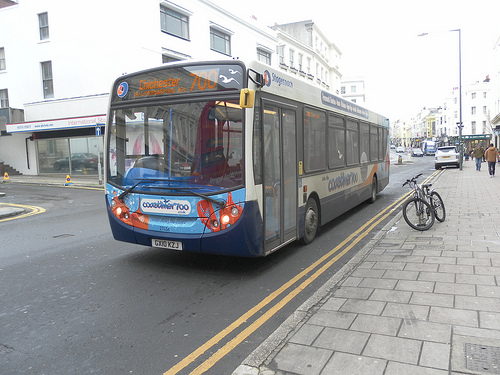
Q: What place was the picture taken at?
A: It was taken at the city.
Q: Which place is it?
A: It is a city.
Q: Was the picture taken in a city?
A: Yes, it was taken in a city.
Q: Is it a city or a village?
A: It is a city.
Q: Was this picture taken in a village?
A: No, the picture was taken in a city.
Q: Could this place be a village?
A: No, it is a city.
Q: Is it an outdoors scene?
A: Yes, it is outdoors.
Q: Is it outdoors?
A: Yes, it is outdoors.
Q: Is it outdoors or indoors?
A: It is outdoors.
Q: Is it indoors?
A: No, it is outdoors.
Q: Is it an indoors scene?
A: No, it is outdoors.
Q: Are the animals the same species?
A: Yes, all the animals are seagulls.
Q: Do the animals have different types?
A: No, all the animals are sea gulls.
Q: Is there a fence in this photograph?
A: No, there are no fences.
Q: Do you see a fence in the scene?
A: No, there are no fences.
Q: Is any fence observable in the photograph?
A: No, there are no fences.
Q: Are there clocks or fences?
A: No, there are no fences or clocks.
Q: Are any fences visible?
A: No, there are no fences.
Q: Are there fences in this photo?
A: No, there are no fences.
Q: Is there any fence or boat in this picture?
A: No, there are no fences or boats.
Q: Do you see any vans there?
A: No, there are no vans.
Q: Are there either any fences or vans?
A: No, there are no vans or fences.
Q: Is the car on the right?
A: Yes, the car is on the right of the image.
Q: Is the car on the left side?
A: No, the car is on the right of the image.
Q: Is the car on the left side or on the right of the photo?
A: The car is on the right of the image.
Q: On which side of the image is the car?
A: The car is on the right of the image.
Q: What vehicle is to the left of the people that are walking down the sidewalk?
A: The vehicle is a car.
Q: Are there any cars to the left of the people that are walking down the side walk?
A: Yes, there is a car to the left of the people.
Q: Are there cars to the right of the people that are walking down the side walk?
A: No, the car is to the left of the people.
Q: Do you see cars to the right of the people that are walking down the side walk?
A: No, the car is to the left of the people.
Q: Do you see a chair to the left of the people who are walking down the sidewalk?
A: No, there is a car to the left of the people.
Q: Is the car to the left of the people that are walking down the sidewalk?
A: Yes, the car is to the left of the people.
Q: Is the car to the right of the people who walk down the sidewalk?
A: No, the car is to the left of the people.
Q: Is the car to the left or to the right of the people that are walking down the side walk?
A: The car is to the left of the people.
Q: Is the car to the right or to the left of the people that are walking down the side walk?
A: The car is to the left of the people.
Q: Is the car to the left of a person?
A: Yes, the car is to the left of a person.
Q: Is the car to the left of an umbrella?
A: No, the car is to the left of a person.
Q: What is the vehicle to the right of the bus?
A: The vehicle is a car.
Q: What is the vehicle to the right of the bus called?
A: The vehicle is a car.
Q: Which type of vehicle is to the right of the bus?
A: The vehicle is a car.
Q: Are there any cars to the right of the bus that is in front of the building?
A: Yes, there is a car to the right of the bus.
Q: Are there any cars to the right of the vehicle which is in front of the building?
A: Yes, there is a car to the right of the bus.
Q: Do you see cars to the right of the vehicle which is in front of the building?
A: Yes, there is a car to the right of the bus.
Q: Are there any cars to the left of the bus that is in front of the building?
A: No, the car is to the right of the bus.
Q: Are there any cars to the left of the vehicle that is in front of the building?
A: No, the car is to the right of the bus.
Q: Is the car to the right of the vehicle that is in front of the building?
A: Yes, the car is to the right of the bus.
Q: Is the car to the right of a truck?
A: No, the car is to the right of the bus.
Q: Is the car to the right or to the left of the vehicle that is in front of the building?
A: The car is to the right of the bus.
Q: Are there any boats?
A: No, there are no boats.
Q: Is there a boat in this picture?
A: No, there are no boats.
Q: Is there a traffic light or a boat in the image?
A: No, there are no boats or traffic lights.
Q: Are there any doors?
A: Yes, there is a door.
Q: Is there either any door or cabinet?
A: Yes, there is a door.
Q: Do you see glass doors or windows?
A: Yes, there is a glass door.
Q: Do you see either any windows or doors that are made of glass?
A: Yes, the door is made of glass.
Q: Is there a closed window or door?
A: Yes, there is a closed door.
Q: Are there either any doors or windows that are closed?
A: Yes, the door is closed.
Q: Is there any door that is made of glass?
A: Yes, there is a door that is made of glass.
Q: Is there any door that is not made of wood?
A: Yes, there is a door that is made of glass.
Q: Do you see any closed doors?
A: Yes, there is a closed door.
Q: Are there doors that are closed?
A: Yes, there is a door that is closed.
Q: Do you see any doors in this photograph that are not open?
A: Yes, there is an closed door.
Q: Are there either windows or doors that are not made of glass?
A: No, there is a door but it is made of glass.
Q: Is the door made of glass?
A: Yes, the door is made of glass.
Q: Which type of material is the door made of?
A: The door is made of glass.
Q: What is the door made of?
A: The door is made of glass.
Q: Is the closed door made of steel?
A: No, the door is made of glass.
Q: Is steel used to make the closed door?
A: No, the door is made of glass.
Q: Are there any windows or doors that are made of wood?
A: No, there is a door but it is made of glass.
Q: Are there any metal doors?
A: No, there is a door but it is made of glass.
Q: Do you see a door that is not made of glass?
A: No, there is a door but it is made of glass.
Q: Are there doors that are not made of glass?
A: No, there is a door but it is made of glass.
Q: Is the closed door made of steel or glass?
A: The door is made of glass.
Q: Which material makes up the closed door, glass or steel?
A: The door is made of glass.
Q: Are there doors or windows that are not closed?
A: No, there is a door but it is closed.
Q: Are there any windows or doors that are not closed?
A: No, there is a door but it is closed.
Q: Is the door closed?
A: Yes, the door is closed.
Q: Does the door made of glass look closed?
A: Yes, the door is closed.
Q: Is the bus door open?
A: No, the door is closed.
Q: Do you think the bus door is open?
A: No, the door is closed.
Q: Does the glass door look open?
A: No, the door is closed.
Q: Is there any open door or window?
A: No, there is a door but it is closed.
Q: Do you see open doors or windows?
A: No, there is a door but it is closed.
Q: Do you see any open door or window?
A: No, there is a door but it is closed.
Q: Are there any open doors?
A: No, there is a door but it is closed.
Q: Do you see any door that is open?
A: No, there is a door but it is closed.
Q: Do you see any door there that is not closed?
A: No, there is a door but it is closed.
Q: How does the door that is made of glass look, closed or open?
A: The door is closed.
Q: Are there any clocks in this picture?
A: No, there are no clocks.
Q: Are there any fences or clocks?
A: No, there are no clocks or fences.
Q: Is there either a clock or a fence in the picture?
A: No, there are no clocks or fences.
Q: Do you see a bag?
A: No, there are no bags.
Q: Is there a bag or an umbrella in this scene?
A: No, there are no bags or umbrellas.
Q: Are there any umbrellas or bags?
A: No, there are no bags or umbrellas.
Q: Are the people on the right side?
A: Yes, the people are on the right of the image.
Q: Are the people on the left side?
A: No, the people are on the right of the image.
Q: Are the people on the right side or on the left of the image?
A: The people are on the right of the image.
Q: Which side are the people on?
A: The people are on the right of the image.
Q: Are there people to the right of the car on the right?
A: Yes, there are people to the right of the car.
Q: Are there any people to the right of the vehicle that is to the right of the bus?
A: Yes, there are people to the right of the car.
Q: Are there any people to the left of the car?
A: No, the people are to the right of the car.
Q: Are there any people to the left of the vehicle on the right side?
A: No, the people are to the right of the car.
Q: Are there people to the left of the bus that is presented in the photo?
A: No, the people are to the right of the bus.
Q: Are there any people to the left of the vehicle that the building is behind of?
A: No, the people are to the right of the bus.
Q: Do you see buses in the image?
A: Yes, there is a bus.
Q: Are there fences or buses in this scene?
A: Yes, there is a bus.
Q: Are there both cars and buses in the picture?
A: Yes, there are both a bus and a car.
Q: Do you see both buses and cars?
A: Yes, there are both a bus and a car.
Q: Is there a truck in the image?
A: No, there are no trucks.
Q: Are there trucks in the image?
A: No, there are no trucks.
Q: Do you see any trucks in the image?
A: No, there are no trucks.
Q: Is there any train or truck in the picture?
A: No, there are no trucks or trains.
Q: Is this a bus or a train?
A: This is a bus.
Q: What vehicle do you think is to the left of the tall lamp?
A: The vehicle is a bus.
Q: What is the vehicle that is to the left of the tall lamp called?
A: The vehicle is a bus.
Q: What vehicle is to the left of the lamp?
A: The vehicle is a bus.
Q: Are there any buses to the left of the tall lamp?
A: Yes, there is a bus to the left of the lamp.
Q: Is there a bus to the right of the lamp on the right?
A: No, the bus is to the left of the lamp.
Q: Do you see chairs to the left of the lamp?
A: No, there is a bus to the left of the lamp.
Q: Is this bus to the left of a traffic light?
A: No, the bus is to the left of a lamp.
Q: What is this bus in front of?
A: The bus is in front of the building.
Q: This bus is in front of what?
A: The bus is in front of the building.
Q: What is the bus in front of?
A: The bus is in front of the building.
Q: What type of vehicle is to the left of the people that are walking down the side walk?
A: The vehicle is a bus.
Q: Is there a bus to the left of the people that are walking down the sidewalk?
A: Yes, there is a bus to the left of the people.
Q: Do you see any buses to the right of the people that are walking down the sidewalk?
A: No, the bus is to the left of the people.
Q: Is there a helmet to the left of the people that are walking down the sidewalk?
A: No, there is a bus to the left of the people.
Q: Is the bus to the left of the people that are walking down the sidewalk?
A: Yes, the bus is to the left of the people.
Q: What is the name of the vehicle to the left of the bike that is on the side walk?
A: The vehicle is a bus.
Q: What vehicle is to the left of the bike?
A: The vehicle is a bus.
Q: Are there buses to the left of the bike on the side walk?
A: Yes, there is a bus to the left of the bike.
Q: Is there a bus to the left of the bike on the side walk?
A: Yes, there is a bus to the left of the bike.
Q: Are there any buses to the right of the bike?
A: No, the bus is to the left of the bike.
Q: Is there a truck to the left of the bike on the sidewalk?
A: No, there is a bus to the left of the bike.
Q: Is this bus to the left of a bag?
A: No, the bus is to the left of the bike.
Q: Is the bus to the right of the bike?
A: No, the bus is to the left of the bike.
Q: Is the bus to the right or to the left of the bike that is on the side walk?
A: The bus is to the left of the bike.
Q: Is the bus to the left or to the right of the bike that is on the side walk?
A: The bus is to the left of the bike.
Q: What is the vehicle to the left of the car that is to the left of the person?
A: The vehicle is a bus.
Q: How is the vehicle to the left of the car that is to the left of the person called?
A: The vehicle is a bus.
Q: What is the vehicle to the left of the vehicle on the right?
A: The vehicle is a bus.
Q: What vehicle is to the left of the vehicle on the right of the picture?
A: The vehicle is a bus.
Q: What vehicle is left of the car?
A: The vehicle is a bus.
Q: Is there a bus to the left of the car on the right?
A: Yes, there is a bus to the left of the car.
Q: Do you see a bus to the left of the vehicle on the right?
A: Yes, there is a bus to the left of the car.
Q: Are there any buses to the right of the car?
A: No, the bus is to the left of the car.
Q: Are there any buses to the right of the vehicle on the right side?
A: No, the bus is to the left of the car.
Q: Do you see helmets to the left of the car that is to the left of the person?
A: No, there is a bus to the left of the car.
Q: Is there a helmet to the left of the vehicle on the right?
A: No, there is a bus to the left of the car.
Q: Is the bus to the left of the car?
A: Yes, the bus is to the left of the car.